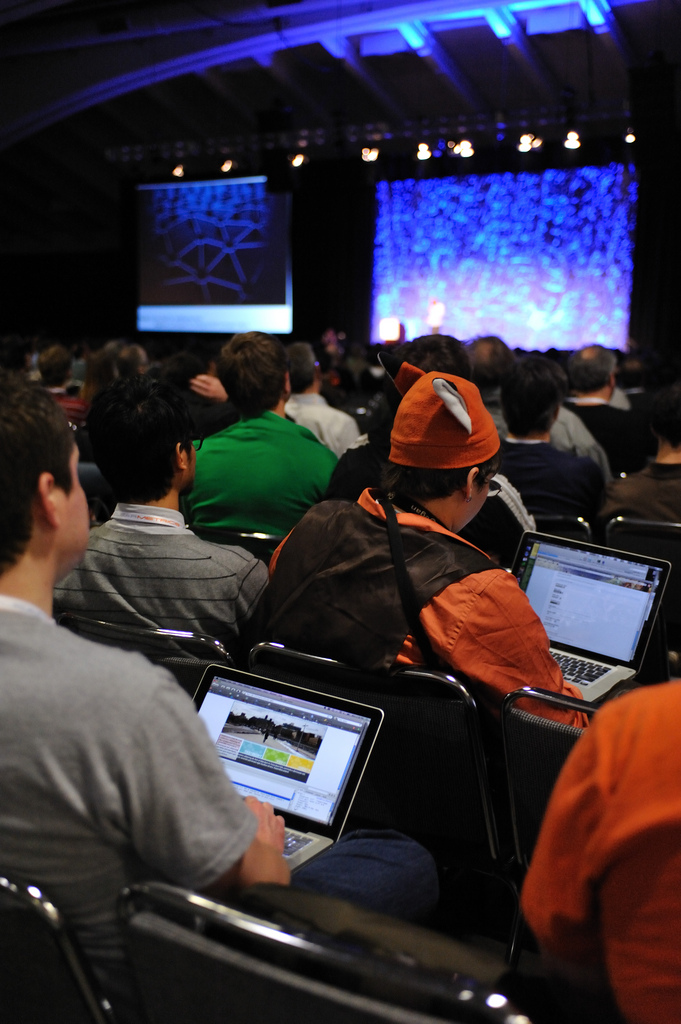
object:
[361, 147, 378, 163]
light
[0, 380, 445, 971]
man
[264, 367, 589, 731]
man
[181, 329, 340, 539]
man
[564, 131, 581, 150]
light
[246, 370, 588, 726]
person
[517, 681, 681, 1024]
person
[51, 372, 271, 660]
person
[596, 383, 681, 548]
person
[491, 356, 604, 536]
person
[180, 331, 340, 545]
person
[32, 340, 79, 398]
person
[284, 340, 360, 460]
person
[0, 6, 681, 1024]
theater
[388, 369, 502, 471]
hat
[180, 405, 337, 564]
polo shirt